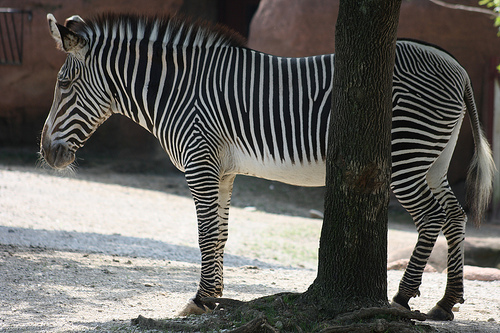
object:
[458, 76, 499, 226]
tail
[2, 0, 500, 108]
building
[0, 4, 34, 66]
attachment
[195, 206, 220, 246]
stripes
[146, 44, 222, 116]
stripes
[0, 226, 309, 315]
shadows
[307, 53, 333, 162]
stripes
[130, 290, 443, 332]
roots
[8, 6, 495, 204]
wall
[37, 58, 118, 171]
face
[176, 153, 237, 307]
legs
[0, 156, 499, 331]
ground structure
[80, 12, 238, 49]
mane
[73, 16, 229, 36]
fringed strips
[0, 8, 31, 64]
container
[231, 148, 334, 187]
belly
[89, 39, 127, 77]
stripes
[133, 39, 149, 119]
stripe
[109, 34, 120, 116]
stripe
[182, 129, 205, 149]
stripe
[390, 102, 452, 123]
stripe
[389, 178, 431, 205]
stripe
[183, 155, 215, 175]
strip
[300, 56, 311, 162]
strip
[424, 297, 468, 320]
foot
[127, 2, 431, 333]
tree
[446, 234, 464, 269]
hole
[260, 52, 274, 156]
stripe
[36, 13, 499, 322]
animal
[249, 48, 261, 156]
stripe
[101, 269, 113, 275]
rock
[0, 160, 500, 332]
ground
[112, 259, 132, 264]
rock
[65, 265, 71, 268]
rock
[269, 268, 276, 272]
rock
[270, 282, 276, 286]
rock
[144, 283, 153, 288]
rock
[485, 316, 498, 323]
rock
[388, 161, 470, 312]
legs